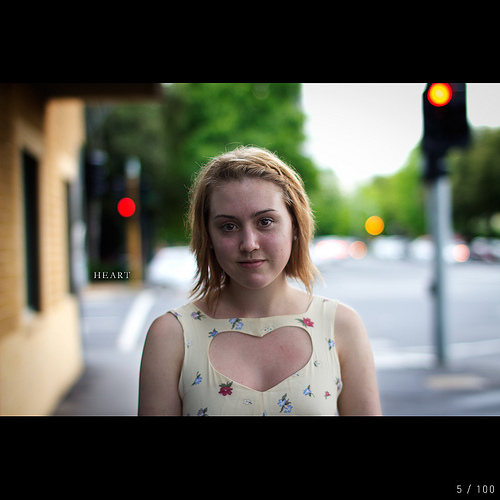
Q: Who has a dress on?
A: The woman.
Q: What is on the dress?
A: A heart opening.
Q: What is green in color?
A: Trees.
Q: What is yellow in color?
A: The light.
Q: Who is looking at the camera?
A: The woman.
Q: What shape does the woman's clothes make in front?
A: A heart.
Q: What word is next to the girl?
A: Heart.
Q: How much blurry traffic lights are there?
A: Three.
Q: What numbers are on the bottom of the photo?
A: 5 and 100.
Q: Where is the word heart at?
A: Next to the girl.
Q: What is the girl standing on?
A: The sidewalk.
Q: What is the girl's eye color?
A: Brown.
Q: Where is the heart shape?
A: On her chest.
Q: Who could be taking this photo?
A: A photographer.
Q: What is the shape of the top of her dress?
A: A heart.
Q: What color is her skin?
A: White.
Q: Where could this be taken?
A: City.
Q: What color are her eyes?
A: Brown.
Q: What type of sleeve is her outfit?
A: Sleeveless.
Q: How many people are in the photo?
A: One.